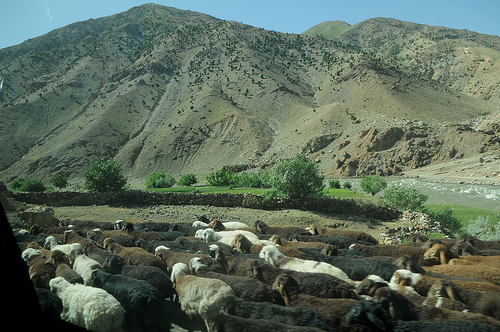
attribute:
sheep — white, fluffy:
[48, 272, 125, 329]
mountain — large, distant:
[2, 1, 499, 192]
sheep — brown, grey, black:
[18, 217, 484, 330]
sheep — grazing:
[41, 220, 381, 314]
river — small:
[333, 167, 483, 207]